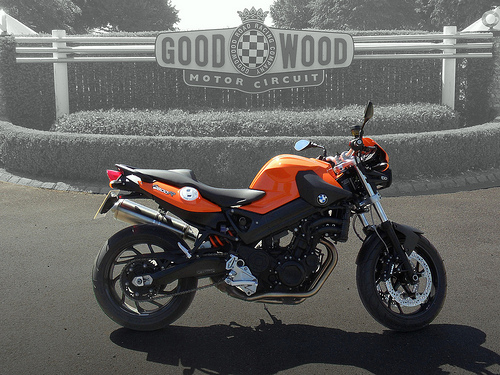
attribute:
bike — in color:
[91, 95, 451, 334]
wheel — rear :
[88, 216, 205, 341]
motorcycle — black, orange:
[81, 96, 454, 338]